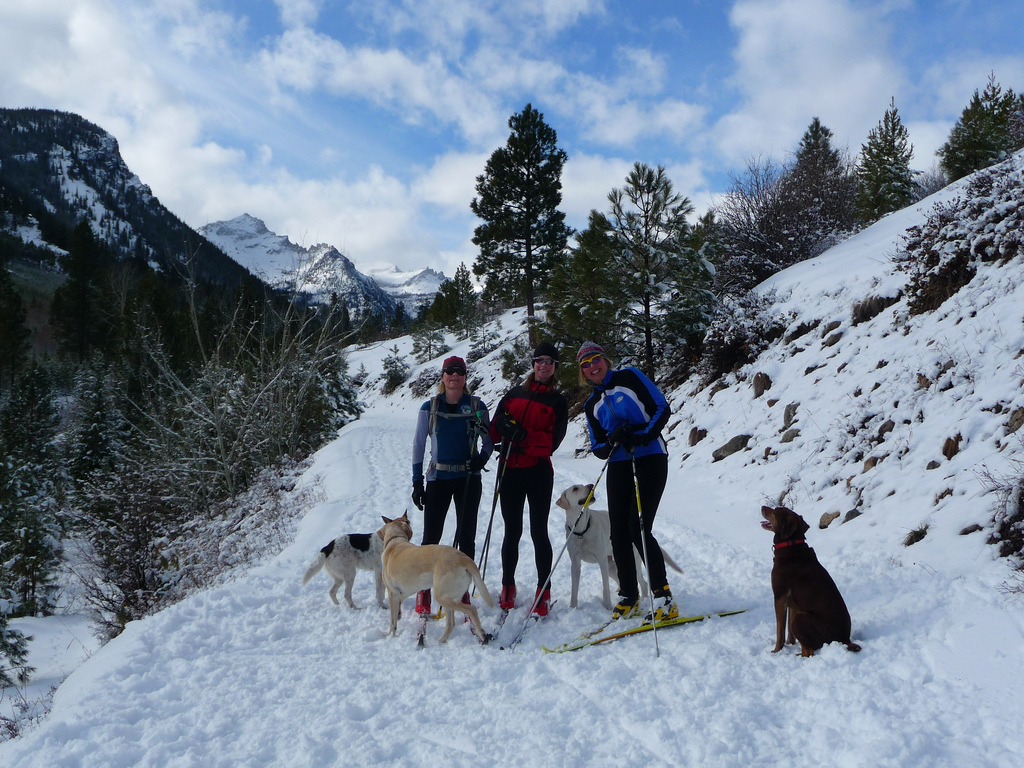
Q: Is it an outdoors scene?
A: Yes, it is outdoors.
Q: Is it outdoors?
A: Yes, it is outdoors.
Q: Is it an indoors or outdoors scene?
A: It is outdoors.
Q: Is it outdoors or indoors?
A: It is outdoors.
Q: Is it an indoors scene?
A: No, it is outdoors.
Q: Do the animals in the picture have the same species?
A: Yes, all the animals are dogs.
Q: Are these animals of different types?
A: No, all the animals are dogs.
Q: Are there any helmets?
A: No, there are no helmets.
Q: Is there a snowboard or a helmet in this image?
A: No, there are no helmets or snowboards.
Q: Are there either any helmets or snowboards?
A: No, there are no helmets or snowboards.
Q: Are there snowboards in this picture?
A: No, there are no snowboards.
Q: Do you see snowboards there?
A: No, there are no snowboards.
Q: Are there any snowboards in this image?
A: No, there are no snowboards.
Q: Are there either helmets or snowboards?
A: No, there are no snowboards or helmets.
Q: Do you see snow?
A: Yes, there is snow.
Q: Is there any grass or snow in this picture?
A: Yes, there is snow.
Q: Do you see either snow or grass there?
A: Yes, there is snow.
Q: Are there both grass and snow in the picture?
A: No, there is snow but no grass.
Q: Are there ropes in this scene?
A: No, there are no ropes.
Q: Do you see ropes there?
A: No, there are no ropes.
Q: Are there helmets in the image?
A: No, there are no helmets.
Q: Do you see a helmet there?
A: No, there are no helmets.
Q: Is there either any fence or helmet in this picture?
A: No, there are no helmets or fences.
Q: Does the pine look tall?
A: Yes, the pine is tall.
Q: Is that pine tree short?
A: No, the pine tree is tall.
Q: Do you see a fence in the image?
A: No, there are no fences.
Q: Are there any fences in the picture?
A: No, there are no fences.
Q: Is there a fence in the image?
A: No, there are no fences.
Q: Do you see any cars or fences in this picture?
A: No, there are no fences or cars.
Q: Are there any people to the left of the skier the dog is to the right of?
A: Yes, there is a person to the left of the skier.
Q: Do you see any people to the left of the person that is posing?
A: Yes, there is a person to the left of the skier.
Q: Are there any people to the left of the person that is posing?
A: Yes, there is a person to the left of the skier.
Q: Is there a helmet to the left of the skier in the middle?
A: No, there is a person to the left of the skier.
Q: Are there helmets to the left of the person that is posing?
A: No, there is a person to the left of the skier.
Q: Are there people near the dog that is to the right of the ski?
A: Yes, there is a person near the dog.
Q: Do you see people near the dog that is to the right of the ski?
A: Yes, there is a person near the dog.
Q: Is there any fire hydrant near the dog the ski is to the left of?
A: No, there is a person near the dog.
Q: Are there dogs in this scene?
A: Yes, there is a dog.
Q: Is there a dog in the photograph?
A: Yes, there is a dog.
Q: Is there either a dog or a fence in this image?
A: Yes, there is a dog.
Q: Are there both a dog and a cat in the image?
A: No, there is a dog but no cats.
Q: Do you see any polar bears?
A: No, there are no polar bears.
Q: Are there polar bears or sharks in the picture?
A: No, there are no polar bears or sharks.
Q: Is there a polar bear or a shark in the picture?
A: No, there are no polar bears or sharks.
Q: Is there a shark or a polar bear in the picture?
A: No, there are no polar bears or sharks.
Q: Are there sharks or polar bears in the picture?
A: No, there are no polar bears or sharks.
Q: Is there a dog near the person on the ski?
A: Yes, there is a dog near the person.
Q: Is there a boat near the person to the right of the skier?
A: No, there is a dog near the person.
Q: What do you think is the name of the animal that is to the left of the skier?
A: The animal is a dog.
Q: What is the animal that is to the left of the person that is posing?
A: The animal is a dog.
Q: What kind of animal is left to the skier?
A: The animal is a dog.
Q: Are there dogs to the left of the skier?
A: Yes, there is a dog to the left of the skier.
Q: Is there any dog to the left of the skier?
A: Yes, there is a dog to the left of the skier.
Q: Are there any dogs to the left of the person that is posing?
A: Yes, there is a dog to the left of the skier.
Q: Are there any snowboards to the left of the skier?
A: No, there is a dog to the left of the skier.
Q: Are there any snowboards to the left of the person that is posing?
A: No, there is a dog to the left of the skier.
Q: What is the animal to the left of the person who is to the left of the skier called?
A: The animal is a dog.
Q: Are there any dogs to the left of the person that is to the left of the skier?
A: Yes, there is a dog to the left of the person.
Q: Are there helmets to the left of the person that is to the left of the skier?
A: No, there is a dog to the left of the person.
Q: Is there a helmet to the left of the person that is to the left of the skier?
A: No, there is a dog to the left of the person.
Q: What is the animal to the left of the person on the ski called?
A: The animal is a dog.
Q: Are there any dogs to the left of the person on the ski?
A: Yes, there is a dog to the left of the person.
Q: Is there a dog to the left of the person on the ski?
A: Yes, there is a dog to the left of the person.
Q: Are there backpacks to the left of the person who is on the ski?
A: No, there is a dog to the left of the person.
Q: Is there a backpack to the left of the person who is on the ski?
A: No, there is a dog to the left of the person.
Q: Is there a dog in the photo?
A: Yes, there is a dog.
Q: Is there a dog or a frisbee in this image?
A: Yes, there is a dog.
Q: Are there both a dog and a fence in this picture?
A: No, there is a dog but no fences.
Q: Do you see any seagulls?
A: No, there are no seagulls.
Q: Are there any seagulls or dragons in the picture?
A: No, there are no seagulls or dragons.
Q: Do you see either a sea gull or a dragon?
A: No, there are no seagulls or dragons.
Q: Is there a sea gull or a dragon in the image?
A: No, there are no seagulls or dragons.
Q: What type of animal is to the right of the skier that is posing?
A: The animal is a dog.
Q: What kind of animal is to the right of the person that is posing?
A: The animal is a dog.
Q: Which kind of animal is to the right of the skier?
A: The animal is a dog.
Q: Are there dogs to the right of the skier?
A: Yes, there is a dog to the right of the skier.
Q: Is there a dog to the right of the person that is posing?
A: Yes, there is a dog to the right of the skier.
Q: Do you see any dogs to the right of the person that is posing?
A: Yes, there is a dog to the right of the skier.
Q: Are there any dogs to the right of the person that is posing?
A: Yes, there is a dog to the right of the skier.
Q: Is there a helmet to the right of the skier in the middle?
A: No, there is a dog to the right of the skier.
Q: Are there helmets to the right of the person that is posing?
A: No, there is a dog to the right of the skier.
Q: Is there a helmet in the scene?
A: No, there are no helmets.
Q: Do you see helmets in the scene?
A: No, there are no helmets.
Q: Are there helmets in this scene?
A: No, there are no helmets.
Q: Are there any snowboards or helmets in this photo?
A: No, there are no helmets or snowboards.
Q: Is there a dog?
A: Yes, there is a dog.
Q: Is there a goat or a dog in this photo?
A: Yes, there is a dog.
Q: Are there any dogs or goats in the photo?
A: Yes, there is a dog.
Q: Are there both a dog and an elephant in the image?
A: No, there is a dog but no elephants.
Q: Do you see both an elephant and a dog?
A: No, there is a dog but no elephants.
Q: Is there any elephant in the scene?
A: No, there are no elephants.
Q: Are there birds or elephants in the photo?
A: No, there are no elephants or birds.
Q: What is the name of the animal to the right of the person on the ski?
A: The animal is a dog.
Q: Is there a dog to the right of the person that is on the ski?
A: Yes, there is a dog to the right of the person.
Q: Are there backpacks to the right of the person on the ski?
A: No, there is a dog to the right of the person.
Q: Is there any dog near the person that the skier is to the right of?
A: Yes, there is a dog near the person.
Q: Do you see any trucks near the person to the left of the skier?
A: No, there is a dog near the person.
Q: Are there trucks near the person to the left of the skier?
A: No, there is a dog near the person.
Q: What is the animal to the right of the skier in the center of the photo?
A: The animal is a dog.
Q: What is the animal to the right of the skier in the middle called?
A: The animal is a dog.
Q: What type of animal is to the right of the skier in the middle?
A: The animal is a dog.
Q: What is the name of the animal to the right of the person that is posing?
A: The animal is a dog.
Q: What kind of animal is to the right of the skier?
A: The animal is a dog.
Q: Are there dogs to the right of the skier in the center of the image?
A: Yes, there is a dog to the right of the skier.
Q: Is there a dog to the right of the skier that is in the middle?
A: Yes, there is a dog to the right of the skier.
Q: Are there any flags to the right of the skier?
A: No, there is a dog to the right of the skier.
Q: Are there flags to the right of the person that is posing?
A: No, there is a dog to the right of the skier.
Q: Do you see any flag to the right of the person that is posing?
A: No, there is a dog to the right of the skier.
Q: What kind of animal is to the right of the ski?
A: The animal is a dog.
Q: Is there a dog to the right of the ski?
A: Yes, there is a dog to the right of the ski.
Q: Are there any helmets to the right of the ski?
A: No, there is a dog to the right of the ski.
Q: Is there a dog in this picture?
A: Yes, there is a dog.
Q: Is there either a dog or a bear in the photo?
A: Yes, there is a dog.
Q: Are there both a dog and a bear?
A: No, there is a dog but no bears.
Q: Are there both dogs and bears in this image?
A: No, there is a dog but no bears.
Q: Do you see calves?
A: No, there are no calves.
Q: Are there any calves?
A: No, there are no calves.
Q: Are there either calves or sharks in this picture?
A: No, there are no calves or sharks.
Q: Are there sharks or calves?
A: No, there are no calves or sharks.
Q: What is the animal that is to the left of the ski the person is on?
A: The animal is a dog.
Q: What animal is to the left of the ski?
A: The animal is a dog.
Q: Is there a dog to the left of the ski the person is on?
A: Yes, there is a dog to the left of the ski.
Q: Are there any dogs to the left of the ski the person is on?
A: Yes, there is a dog to the left of the ski.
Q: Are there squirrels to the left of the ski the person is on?
A: No, there is a dog to the left of the ski.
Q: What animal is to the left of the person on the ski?
A: The animal is a dog.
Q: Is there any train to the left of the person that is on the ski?
A: No, there is a dog to the left of the person.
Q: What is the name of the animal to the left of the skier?
A: The animal is a dog.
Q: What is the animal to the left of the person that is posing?
A: The animal is a dog.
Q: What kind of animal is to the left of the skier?
A: The animal is a dog.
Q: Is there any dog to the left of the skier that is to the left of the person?
A: Yes, there is a dog to the left of the skier.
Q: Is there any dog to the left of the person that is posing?
A: Yes, there is a dog to the left of the skier.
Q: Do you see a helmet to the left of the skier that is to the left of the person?
A: No, there is a dog to the left of the skier.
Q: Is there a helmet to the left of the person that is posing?
A: No, there is a dog to the left of the skier.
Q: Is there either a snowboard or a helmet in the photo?
A: No, there are no helmets or snowboards.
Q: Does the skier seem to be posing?
A: Yes, the skier is posing.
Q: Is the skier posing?
A: Yes, the skier is posing.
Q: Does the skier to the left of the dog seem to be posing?
A: Yes, the skier is posing.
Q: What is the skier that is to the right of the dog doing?
A: The skier is posing.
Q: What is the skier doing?
A: The skier is posing.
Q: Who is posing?
A: The skier is posing.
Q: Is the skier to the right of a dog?
A: Yes, the skier is to the right of a dog.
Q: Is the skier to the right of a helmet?
A: No, the skier is to the right of a dog.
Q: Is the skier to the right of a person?
A: Yes, the skier is to the right of a person.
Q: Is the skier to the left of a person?
A: No, the skier is to the right of a person.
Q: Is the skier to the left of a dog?
A: Yes, the skier is to the left of a dog.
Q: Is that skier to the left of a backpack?
A: No, the skier is to the left of a dog.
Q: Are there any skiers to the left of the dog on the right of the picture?
A: Yes, there is a skier to the left of the dog.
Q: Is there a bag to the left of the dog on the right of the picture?
A: No, there is a skier to the left of the dog.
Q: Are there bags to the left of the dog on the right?
A: No, there is a skier to the left of the dog.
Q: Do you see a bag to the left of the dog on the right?
A: No, there is a skier to the left of the dog.